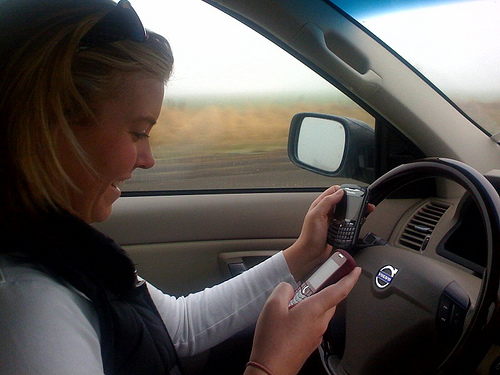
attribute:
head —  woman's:
[1, 0, 176, 225]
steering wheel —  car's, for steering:
[312, 148, 499, 373]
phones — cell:
[277, 175, 393, 295]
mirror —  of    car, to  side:
[269, 94, 430, 195]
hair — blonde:
[4, 3, 151, 210]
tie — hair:
[240, 357, 278, 374]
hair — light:
[3, 2, 105, 182]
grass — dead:
[151, 104, 373, 144]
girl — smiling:
[1, 0, 374, 374]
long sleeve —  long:
[136, 249, 300, 358]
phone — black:
[321, 179, 373, 248]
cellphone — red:
[331, 181, 366, 251]